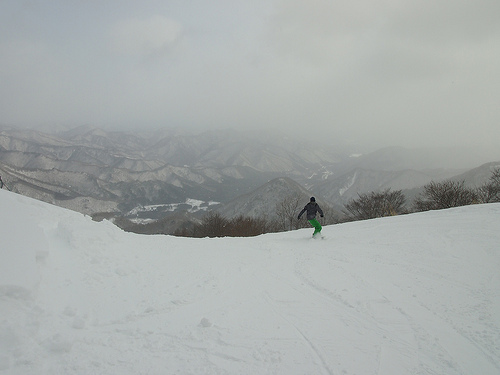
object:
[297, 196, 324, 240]
man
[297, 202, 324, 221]
jacket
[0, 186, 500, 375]
snow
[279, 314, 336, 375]
tracks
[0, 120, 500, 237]
mountains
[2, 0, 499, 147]
sky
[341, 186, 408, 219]
trees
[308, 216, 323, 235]
pants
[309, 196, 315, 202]
hat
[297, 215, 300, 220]
gloves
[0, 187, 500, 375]
ground